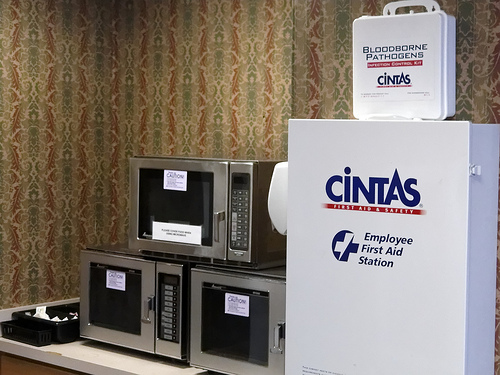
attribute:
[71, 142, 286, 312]
microwave — three, stacked, steel, grey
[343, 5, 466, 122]
kit — first aid, small, pathogen, sanitize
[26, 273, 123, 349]
basket — empty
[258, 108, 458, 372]
case — first aid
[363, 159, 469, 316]
station — first aid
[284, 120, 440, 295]
first aid — employee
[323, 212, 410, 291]
box — first aid, white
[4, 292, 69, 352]
tray — black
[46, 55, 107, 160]
wallpaper — tan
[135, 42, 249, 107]
curtain — multi-colored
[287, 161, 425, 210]
letter — blue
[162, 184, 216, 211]
glass — black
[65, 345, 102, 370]
top — white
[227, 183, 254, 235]
switch — control